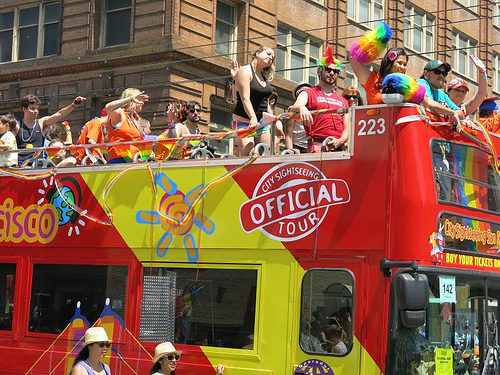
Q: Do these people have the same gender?
A: No, they are both male and female.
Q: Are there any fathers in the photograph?
A: No, there are no fathers.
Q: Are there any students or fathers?
A: No, there are no fathers or students.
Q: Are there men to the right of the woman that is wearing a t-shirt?
A: Yes, there is a man to the right of the woman.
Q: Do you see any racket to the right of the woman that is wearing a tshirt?
A: No, there is a man to the right of the woman.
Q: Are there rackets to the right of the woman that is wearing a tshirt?
A: No, there is a man to the right of the woman.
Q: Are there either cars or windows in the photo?
A: Yes, there is a window.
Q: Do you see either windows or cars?
A: Yes, there is a window.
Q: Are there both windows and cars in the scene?
A: No, there is a window but no cars.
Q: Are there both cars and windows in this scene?
A: No, there is a window but no cars.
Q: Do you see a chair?
A: No, there are no chairs.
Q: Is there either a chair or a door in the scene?
A: No, there are no chairs or doors.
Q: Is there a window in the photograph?
A: Yes, there is a window.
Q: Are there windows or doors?
A: Yes, there is a window.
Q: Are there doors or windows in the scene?
A: Yes, there is a window.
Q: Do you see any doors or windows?
A: Yes, there is a window.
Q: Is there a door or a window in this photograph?
A: Yes, there is a window.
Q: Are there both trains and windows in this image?
A: No, there is a window but no trains.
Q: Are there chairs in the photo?
A: No, there are no chairs.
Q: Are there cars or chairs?
A: No, there are no chairs or cars.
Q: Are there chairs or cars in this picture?
A: No, there are no chairs or cars.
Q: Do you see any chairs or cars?
A: No, there are no chairs or cars.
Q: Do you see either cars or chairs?
A: No, there are no chairs or cars.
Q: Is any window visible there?
A: Yes, there is a window.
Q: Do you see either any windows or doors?
A: Yes, there is a window.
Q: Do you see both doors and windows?
A: No, there is a window but no doors.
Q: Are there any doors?
A: No, there are no doors.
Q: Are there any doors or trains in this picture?
A: No, there are no doors or trains.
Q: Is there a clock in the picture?
A: No, there are no clocks.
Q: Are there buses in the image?
A: Yes, there is a bus.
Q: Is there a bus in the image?
A: Yes, there is a bus.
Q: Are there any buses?
A: Yes, there is a bus.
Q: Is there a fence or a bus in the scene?
A: Yes, there is a bus.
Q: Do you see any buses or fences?
A: Yes, there is a bus.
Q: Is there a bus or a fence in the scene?
A: Yes, there is a bus.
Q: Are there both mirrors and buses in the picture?
A: Yes, there are both a bus and a mirror.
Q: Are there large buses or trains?
A: Yes, there is a large bus.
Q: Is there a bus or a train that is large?
A: Yes, the bus is large.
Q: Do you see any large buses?
A: Yes, there is a large bus.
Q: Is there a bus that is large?
A: Yes, there is a bus that is large.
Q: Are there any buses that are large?
A: Yes, there is a bus that is large.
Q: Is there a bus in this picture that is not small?
A: Yes, there is a large bus.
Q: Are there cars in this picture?
A: No, there are no cars.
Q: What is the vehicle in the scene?
A: The vehicle is a bus.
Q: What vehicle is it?
A: The vehicle is a bus.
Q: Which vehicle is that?
A: This is a bus.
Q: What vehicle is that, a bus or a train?
A: This is a bus.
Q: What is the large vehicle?
A: The vehicle is a bus.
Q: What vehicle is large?
A: The vehicle is a bus.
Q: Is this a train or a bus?
A: This is a bus.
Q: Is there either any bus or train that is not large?
A: No, there is a bus but it is large.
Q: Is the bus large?
A: Yes, the bus is large.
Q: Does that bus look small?
A: No, the bus is large.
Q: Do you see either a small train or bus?
A: No, there is a bus but it is large.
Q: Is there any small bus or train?
A: No, there is a bus but it is large.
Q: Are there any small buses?
A: No, there is a bus but it is large.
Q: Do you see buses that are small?
A: No, there is a bus but it is large.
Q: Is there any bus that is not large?
A: No, there is a bus but it is large.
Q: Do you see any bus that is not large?
A: No, there is a bus but it is large.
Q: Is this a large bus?
A: Yes, this is a large bus.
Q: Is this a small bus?
A: No, this is a large bus.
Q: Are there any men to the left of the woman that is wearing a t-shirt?
A: Yes, there is a man to the left of the woman.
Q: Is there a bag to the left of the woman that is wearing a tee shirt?
A: No, there is a man to the left of the woman.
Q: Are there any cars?
A: No, there are no cars.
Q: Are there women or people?
A: Yes, there is a woman.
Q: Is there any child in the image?
A: No, there are no children.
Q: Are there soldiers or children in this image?
A: No, there are no children or soldiers.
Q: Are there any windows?
A: Yes, there is a window.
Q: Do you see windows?
A: Yes, there is a window.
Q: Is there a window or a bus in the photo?
A: Yes, there is a window.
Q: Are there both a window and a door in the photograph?
A: No, there is a window but no doors.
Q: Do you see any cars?
A: No, there are no cars.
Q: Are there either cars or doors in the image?
A: No, there are no cars or doors.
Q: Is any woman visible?
A: Yes, there is a woman.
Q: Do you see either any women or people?
A: Yes, there is a woman.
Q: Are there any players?
A: No, there are no players.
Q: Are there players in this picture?
A: No, there are no players.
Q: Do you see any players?
A: No, there are no players.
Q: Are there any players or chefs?
A: No, there are no players or chefs.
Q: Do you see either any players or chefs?
A: No, there are no players or chefs.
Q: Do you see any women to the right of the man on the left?
A: Yes, there is a woman to the right of the man.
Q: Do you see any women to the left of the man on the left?
A: No, the woman is to the right of the man.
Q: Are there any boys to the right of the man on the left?
A: No, there is a woman to the right of the man.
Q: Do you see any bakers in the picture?
A: No, there are no bakers.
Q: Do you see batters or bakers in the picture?
A: No, there are no bakers or batters.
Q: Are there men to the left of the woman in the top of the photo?
A: Yes, there is a man to the left of the woman.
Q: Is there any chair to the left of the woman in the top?
A: No, there is a man to the left of the woman.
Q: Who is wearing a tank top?
A: The man is wearing a tank top.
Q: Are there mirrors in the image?
A: Yes, there is a mirror.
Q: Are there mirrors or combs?
A: Yes, there is a mirror.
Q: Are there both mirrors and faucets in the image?
A: No, there is a mirror but no faucets.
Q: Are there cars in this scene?
A: No, there are no cars.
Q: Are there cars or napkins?
A: No, there are no cars or napkins.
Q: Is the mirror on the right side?
A: Yes, the mirror is on the right of the image.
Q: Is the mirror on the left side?
A: No, the mirror is on the right of the image.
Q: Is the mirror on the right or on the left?
A: The mirror is on the right of the image.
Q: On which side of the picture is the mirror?
A: The mirror is on the right of the image.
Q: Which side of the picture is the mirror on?
A: The mirror is on the right of the image.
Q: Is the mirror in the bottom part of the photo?
A: Yes, the mirror is in the bottom of the image.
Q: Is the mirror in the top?
A: No, the mirror is in the bottom of the image.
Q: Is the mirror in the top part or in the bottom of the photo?
A: The mirror is in the bottom of the image.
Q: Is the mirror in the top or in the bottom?
A: The mirror is in the bottom of the image.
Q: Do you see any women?
A: Yes, there is a woman.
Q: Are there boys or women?
A: Yes, there is a woman.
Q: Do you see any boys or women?
A: Yes, there is a woman.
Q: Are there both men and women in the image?
A: Yes, there are both a woman and a man.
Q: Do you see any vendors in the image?
A: No, there are no vendors.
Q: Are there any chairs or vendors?
A: No, there are no vendors or chairs.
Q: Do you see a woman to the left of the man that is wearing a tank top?
A: Yes, there is a woman to the left of the man.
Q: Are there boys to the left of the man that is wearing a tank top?
A: No, there is a woman to the left of the man.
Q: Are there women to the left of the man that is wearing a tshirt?
A: Yes, there is a woman to the left of the man.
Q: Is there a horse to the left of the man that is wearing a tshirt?
A: No, there is a woman to the left of the man.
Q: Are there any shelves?
A: No, there are no shelves.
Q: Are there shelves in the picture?
A: No, there are no shelves.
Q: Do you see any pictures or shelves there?
A: No, there are no shelves or pictures.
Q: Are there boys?
A: No, there are no boys.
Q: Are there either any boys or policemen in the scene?
A: No, there are no boys or policemen.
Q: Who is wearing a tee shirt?
A: The man is wearing a tee shirt.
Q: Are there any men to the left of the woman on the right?
A: Yes, there is a man to the left of the woman.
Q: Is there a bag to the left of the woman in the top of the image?
A: No, there is a man to the left of the woman.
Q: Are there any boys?
A: No, there are no boys.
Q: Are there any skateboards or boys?
A: No, there are no boys or skateboards.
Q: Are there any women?
A: Yes, there is a woman.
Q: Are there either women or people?
A: Yes, there is a woman.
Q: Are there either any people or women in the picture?
A: Yes, there is a woman.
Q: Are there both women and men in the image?
A: Yes, there are both a woman and a man.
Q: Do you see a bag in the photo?
A: No, there are no bags.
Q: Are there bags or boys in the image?
A: No, there are no bags or boys.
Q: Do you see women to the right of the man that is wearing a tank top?
A: Yes, there is a woman to the right of the man.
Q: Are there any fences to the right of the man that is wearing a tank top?
A: No, there is a woman to the right of the man.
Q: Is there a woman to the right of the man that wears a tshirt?
A: Yes, there is a woman to the right of the man.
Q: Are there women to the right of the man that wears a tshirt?
A: Yes, there is a woman to the right of the man.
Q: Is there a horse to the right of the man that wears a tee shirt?
A: No, there is a woman to the right of the man.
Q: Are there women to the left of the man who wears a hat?
A: Yes, there is a woman to the left of the man.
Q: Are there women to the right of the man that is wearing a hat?
A: No, the woman is to the left of the man.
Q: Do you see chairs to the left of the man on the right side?
A: No, there is a woman to the left of the man.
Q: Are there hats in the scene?
A: Yes, there is a hat.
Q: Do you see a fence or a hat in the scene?
A: Yes, there is a hat.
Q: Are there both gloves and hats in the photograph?
A: No, there is a hat but no gloves.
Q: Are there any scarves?
A: No, there are no scarves.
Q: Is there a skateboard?
A: No, there are no skateboards.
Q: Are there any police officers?
A: No, there are no police officers.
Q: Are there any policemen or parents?
A: No, there are no policemen or parents.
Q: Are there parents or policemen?
A: No, there are no policemen or parents.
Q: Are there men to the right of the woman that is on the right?
A: Yes, there is a man to the right of the woman.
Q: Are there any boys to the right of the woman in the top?
A: No, there is a man to the right of the woman.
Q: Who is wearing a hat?
A: The man is wearing a hat.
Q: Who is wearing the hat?
A: The man is wearing a hat.